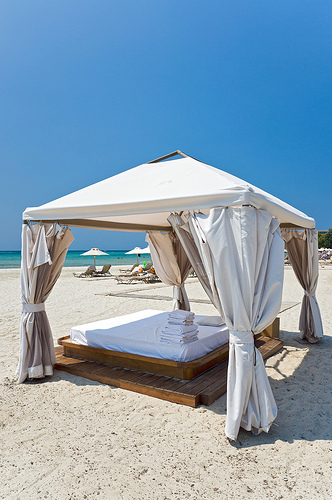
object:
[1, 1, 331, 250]
blue sky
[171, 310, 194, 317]
towel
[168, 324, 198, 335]
towel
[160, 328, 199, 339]
towel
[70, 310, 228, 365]
mattress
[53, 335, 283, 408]
platform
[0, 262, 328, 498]
beach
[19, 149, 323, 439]
tent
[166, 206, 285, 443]
curtains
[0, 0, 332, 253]
clouds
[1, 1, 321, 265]
sky